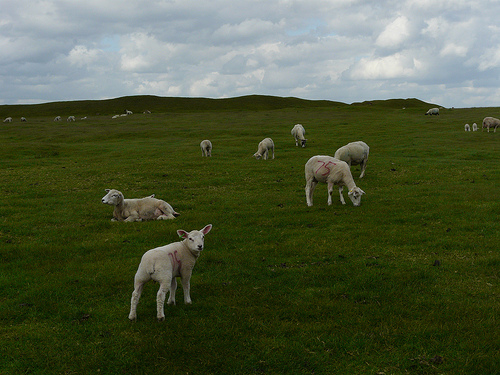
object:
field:
[9, 117, 499, 369]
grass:
[2, 102, 498, 372]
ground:
[0, 104, 500, 372]